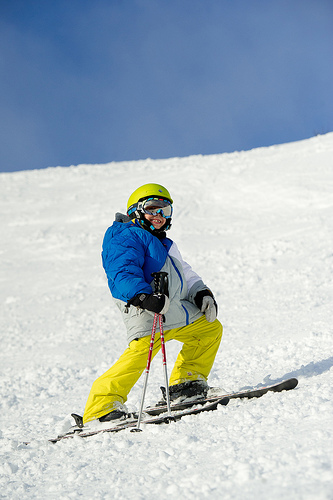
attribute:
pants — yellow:
[81, 313, 223, 421]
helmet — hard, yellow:
[125, 183, 174, 208]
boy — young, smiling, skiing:
[80, 183, 223, 430]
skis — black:
[50, 377, 298, 444]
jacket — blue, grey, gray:
[100, 214, 217, 343]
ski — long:
[52, 396, 230, 443]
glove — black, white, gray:
[197, 295, 219, 322]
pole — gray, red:
[158, 317, 174, 416]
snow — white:
[1, 131, 332, 499]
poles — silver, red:
[130, 312, 174, 431]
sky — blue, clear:
[0, 1, 332, 172]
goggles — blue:
[139, 197, 172, 213]